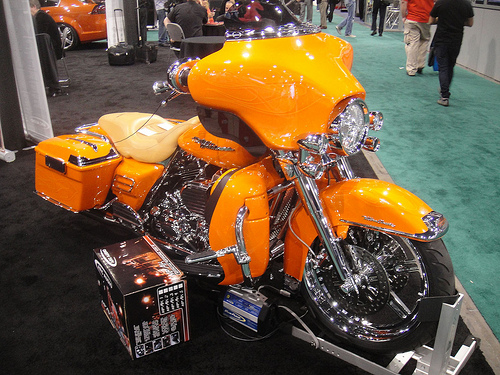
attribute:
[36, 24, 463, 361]
motorcycle — yellow, yellwo, shinning, shining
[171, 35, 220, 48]
tablecloth — black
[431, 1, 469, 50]
shirt — black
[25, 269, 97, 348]
floor — black, carpeted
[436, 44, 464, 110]
pants — black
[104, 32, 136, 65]
bag — black